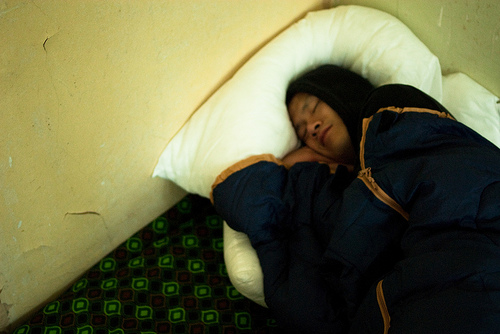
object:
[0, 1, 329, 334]
wall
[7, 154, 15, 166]
stain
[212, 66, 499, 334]
woman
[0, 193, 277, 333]
carpet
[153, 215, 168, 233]
pattern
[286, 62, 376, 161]
head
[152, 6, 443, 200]
pillow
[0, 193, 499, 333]
floor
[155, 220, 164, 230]
circle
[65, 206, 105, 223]
hole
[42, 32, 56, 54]
hole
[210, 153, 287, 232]
strip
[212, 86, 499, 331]
coat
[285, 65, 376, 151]
hair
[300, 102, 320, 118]
eyes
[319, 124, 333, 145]
lipstick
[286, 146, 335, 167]
hand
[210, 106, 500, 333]
bag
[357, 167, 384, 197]
zipper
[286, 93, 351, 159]
face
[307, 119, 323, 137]
nose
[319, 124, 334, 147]
mouth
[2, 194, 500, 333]
ground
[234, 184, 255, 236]
paint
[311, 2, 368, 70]
corner